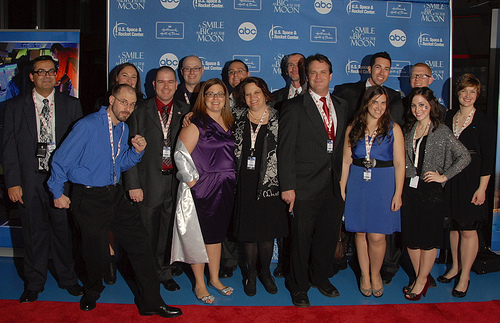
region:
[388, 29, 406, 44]
logo for ABC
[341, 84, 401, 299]
long haired woman wearing a blue dress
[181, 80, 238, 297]
woman wearing glasses and a purple dress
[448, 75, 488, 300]
woman on the side wearing a black dress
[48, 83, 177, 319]
man wearing a blue shirt and black pants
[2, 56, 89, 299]
man on the end wearing glasses and a necktie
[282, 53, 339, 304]
man in the front row wearing a red tie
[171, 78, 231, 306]
woman holding a white shiny wrap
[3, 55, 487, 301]
group of people posing for a photo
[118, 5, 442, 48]
blue and white background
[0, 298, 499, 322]
a red carpet at an event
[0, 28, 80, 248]
a large banner in the background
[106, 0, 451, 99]
a large banner of sponsors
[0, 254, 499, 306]
a blue floor at the event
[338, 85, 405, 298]
a lady attending the event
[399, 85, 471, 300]
a lady attending the event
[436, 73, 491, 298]
a lady attending the event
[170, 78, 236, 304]
a lady attending the event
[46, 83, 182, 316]
a man attending the event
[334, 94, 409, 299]
Woman wearing a blue dress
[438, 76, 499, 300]
Woman wearing a black dress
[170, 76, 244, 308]
Woman wearing a purple dress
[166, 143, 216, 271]
Wrap around woman's arm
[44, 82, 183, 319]
Man wearing a blue shirt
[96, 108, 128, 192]
Tag around man's next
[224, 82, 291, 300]
Woman wearing a black dress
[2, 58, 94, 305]
Man wearing a black suit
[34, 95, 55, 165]
Tie around man's neck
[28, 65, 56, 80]
Glasses on man's face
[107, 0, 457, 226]
Blue background behind people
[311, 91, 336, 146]
Red tie on man's neck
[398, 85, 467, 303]
Woman wearing a gray sweater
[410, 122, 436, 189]
Tag around woman's neck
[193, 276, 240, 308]
Sandles on woman's feet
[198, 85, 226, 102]
Glasses on woman's face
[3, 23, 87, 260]
Sign behind the man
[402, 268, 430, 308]
Hills on the woman's feet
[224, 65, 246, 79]
Glasses on man's face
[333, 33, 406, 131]
Man wearing a black suit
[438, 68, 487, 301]
This is a person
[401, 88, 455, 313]
This is a person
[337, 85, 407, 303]
This is a person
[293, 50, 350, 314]
This is a person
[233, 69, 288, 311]
This is a person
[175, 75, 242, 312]
This is a person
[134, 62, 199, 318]
This is a person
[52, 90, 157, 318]
This is a person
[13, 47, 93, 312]
This is a person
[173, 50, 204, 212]
This is a person